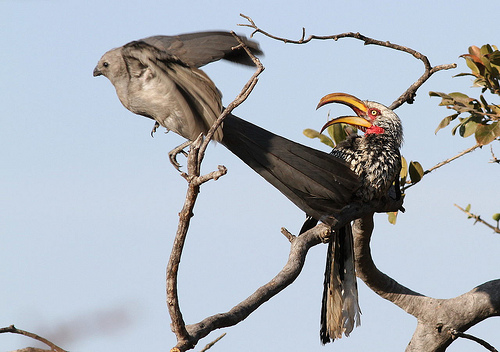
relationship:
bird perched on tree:
[91, 27, 378, 226] [3, 13, 498, 349]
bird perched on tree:
[314, 91, 413, 343] [3, 13, 498, 349]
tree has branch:
[3, 13, 498, 349] [233, 6, 459, 114]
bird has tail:
[314, 91, 413, 343] [318, 221, 366, 350]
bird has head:
[91, 27, 378, 226] [92, 46, 127, 81]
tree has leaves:
[3, 13, 498, 349] [425, 42, 500, 243]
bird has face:
[314, 91, 413, 343] [363, 100, 388, 142]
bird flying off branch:
[91, 27, 378, 226] [162, 31, 268, 352]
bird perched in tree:
[314, 91, 413, 343] [3, 13, 498, 349]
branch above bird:
[233, 6, 459, 114] [314, 91, 413, 343]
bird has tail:
[91, 27, 378, 226] [220, 99, 379, 230]